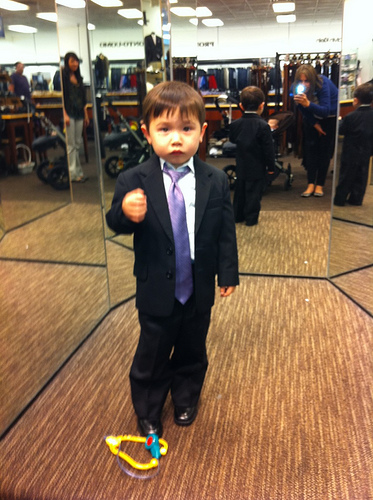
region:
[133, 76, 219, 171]
A boy with black hair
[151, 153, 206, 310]
A boy in a purple tie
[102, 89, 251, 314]
A boy in a coat and tie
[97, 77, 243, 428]
A little boy in a dress suit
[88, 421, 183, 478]
A yellow child's toy on the floor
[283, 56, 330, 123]
A woman taking a picture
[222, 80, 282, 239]
The reflection of a boy in a mirror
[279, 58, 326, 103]
A blond woman holding a camera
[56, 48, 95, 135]
The reflection of a woman in a mirror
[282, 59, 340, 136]
The reflection of a woman in a blue sweater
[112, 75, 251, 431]
boy in black suit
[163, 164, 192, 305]
purple tie on shirt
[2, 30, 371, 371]
mirror with four panels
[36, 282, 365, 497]
brown carpet on floor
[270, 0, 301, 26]
glowing lights on ceiling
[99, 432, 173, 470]
blue and yellow toy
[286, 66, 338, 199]
bending woman with camera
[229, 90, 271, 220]
back of boy in mirror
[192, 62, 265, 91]
rack of suits against wall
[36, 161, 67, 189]
two wheels on stroller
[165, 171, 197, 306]
the purple tie on the little boy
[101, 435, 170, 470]
the stethoscope on the ground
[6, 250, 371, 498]
the flooring in the room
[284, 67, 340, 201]
the woman taking the picture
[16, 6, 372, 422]
the mirrors in the room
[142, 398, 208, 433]
the little boy's shoes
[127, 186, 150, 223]
the little boy's hand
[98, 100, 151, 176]
the stroller in the background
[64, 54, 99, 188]
the woman standing by the stroller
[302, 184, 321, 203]
the women's feet in the background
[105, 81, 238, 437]
the small child wearing a suit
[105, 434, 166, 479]
the toy on the ground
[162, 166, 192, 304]
the toy around the child's neck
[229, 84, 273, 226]
the reflection of the child in the mirror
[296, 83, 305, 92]
the reflection of the flash in the mirror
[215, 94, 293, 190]
the baby stroller with the baby in it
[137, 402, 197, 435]
the dress shoes on the small child's feet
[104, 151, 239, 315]
the dress suit jacket on the small child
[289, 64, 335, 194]
the reflection of the woman holding the camera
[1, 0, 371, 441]
the mirrors behind the small child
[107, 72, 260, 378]
a little boy trying on a tuxedo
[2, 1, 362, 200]
all-around mirrors of a dressing room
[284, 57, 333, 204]
reflection of a person taking a photo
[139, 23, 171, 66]
a tuxedo jacket on a mannequine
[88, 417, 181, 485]
a child's toy on the floor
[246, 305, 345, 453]
brown carpet of a dressing room floor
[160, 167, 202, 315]
an indigo colored tie of a suit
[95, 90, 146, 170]
reflection of a child's stroller in the mirror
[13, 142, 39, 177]
a display basket on the floor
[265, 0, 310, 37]
lights in the ceiling of a store